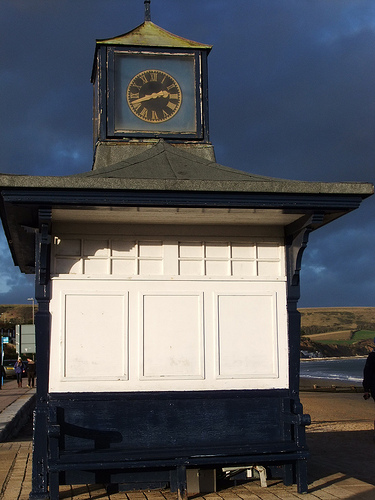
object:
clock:
[108, 56, 196, 133]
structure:
[2, 3, 375, 499]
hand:
[132, 96, 153, 106]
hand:
[154, 91, 170, 96]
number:
[150, 70, 158, 83]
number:
[139, 74, 148, 84]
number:
[131, 81, 142, 91]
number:
[130, 92, 140, 100]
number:
[140, 106, 148, 118]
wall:
[48, 233, 289, 395]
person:
[14, 356, 25, 387]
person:
[25, 356, 37, 390]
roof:
[0, 140, 374, 275]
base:
[24, 452, 324, 499]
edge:
[22, 206, 46, 500]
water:
[297, 353, 375, 384]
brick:
[3, 484, 24, 499]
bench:
[29, 389, 313, 497]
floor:
[0, 421, 375, 499]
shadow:
[305, 431, 373, 499]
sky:
[2, 0, 374, 307]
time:
[129, 90, 177, 105]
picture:
[1, 1, 374, 498]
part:
[0, 221, 41, 312]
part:
[1, 439, 32, 500]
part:
[127, 68, 183, 124]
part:
[0, 176, 373, 193]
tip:
[142, 0, 155, 22]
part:
[31, 375, 36, 389]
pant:
[27, 371, 37, 388]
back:
[14, 323, 38, 357]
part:
[297, 463, 307, 493]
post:
[285, 234, 307, 494]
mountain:
[298, 308, 373, 354]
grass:
[1, 303, 37, 324]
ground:
[0, 305, 372, 498]